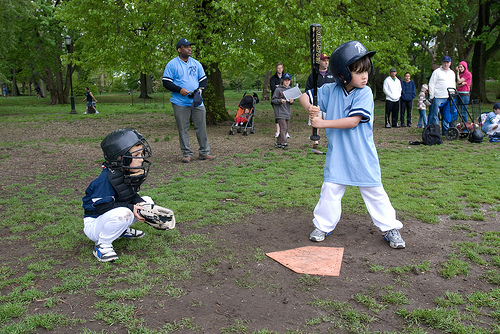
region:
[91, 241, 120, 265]
the boy's right blue shoe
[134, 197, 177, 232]
the catcher's mitt.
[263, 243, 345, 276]
orange home plate on the ground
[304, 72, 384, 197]
the boys' light blue shirt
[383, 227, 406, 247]
the boy's left shoe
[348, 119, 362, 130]
the boy's left elbow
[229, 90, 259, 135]
little child in an orange stroller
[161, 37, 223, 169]
man in blue standing and holding a mitt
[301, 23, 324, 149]
black baseball bat the boy is holding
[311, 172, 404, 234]
white pants the boy is wearing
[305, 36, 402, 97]
boy wearing black helmet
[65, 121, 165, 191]
boy wearing black helmet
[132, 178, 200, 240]
boy holding white glove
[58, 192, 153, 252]
boy wearing white pants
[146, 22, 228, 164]
man wearing blue shirt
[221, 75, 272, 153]
orange and black stroller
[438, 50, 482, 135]
lady wearing pink top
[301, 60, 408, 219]
boy wearing blue shirt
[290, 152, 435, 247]
boy wearing white pants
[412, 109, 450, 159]
black back pack on ground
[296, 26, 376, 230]
a young boy holding a bat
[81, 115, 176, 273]
a young boy squatted down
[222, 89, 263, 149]
a small child in a stroller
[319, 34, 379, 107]
a young boy wearing a helmet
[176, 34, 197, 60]
a man wearing a baseball hat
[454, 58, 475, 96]
a person wearing a sweatshirt with a hood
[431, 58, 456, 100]
a man wearing a white shirt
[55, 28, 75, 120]
a post with a light on it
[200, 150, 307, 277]
patches of grass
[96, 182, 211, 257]
a child wearing a baseball glove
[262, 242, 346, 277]
White home plate on ground.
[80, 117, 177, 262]
Little boy playing catcher position.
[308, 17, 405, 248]
Kid holding bat.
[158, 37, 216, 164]
Coach watching game.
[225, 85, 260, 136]
Red and black stroller.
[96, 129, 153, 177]
Black catching helmet.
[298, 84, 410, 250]
Light blue and white baseball uniform.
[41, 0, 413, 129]
Tree with bright green leaves.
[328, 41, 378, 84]
Dark blue helmet with white letter.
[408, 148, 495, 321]
Patchy grass and dirt ground.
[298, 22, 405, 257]
Child preparing to hit ball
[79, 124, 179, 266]
Child in catcher's stance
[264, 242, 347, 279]
Home plate for ball game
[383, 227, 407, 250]
Foot of ball player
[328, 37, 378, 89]
Head of Ball player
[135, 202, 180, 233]
Catcher's mitt in child's hand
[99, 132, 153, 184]
Catcher's mask on child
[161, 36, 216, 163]
Man watching ball game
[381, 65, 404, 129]
Man watching ball game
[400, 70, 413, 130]
Person watching ball game